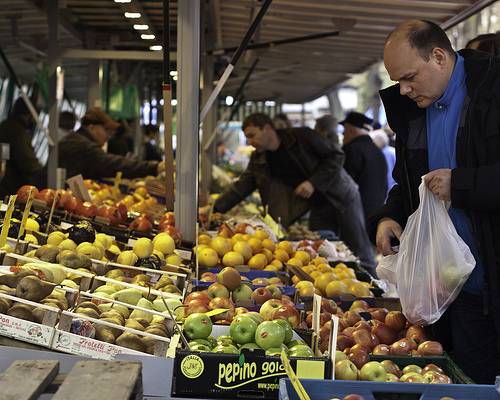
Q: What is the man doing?
A: Reaching for fruit.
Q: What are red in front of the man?
A: Apples.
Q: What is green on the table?
A: Apples.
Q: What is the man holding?
A: A plastic bag.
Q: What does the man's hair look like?
A: Dark and balding.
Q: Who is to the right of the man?
A: A man in a brown jacket.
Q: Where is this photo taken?
A: Farmers market.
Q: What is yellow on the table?
A: Lemons.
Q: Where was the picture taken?
A: At a fruit market.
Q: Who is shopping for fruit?
A: Customers.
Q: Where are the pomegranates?
A: Behind the lemons.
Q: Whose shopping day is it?
A: The mens.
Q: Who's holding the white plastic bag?
A: The man in the blue shirt.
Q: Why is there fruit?
A: Market.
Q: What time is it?
A: Daytime.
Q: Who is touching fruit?
A: People.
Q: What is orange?
A: Oranges.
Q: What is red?
A: Apples.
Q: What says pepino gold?
A: Sign.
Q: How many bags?
A: 1.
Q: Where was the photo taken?
A: Outdoor food market.